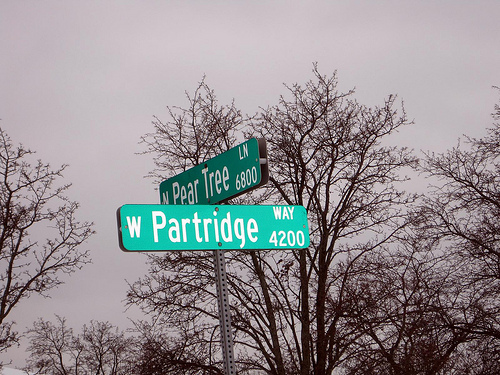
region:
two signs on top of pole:
[107, 125, 318, 370]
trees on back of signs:
[2, 42, 493, 373]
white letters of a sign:
[108, 193, 316, 260]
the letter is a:
[165, 215, 182, 249]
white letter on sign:
[125, 213, 142, 238]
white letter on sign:
[151, 208, 167, 245]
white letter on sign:
[166, 215, 181, 243]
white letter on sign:
[180, 216, 190, 243]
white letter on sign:
[190, 208, 202, 242]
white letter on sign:
[202, 215, 214, 245]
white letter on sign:
[211, 208, 223, 242]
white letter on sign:
[219, 210, 234, 243]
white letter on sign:
[232, 216, 247, 249]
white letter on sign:
[244, 215, 261, 243]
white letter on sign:
[160, 190, 171, 204]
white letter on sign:
[171, 180, 180, 205]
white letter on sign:
[178, 186, 188, 203]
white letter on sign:
[186, 180, 195, 204]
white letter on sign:
[191, 175, 201, 201]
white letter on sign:
[207, 170, 217, 196]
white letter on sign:
[212, 167, 223, 194]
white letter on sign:
[219, 166, 231, 194]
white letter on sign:
[237, 145, 244, 163]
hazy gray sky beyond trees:
[2, 2, 497, 374]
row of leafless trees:
[2, 59, 498, 374]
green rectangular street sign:
[110, 200, 317, 259]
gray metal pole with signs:
[201, 220, 247, 374]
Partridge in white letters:
[147, 208, 262, 250]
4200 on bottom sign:
[267, 228, 306, 253]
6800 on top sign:
[232, 162, 258, 194]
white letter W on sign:
[122, 213, 144, 243]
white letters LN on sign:
[231, 138, 251, 163]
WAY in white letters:
[267, 203, 297, 225]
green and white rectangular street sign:
[108, 198, 312, 257]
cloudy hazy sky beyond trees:
[2, 3, 497, 372]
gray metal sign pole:
[206, 238, 245, 372]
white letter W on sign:
[121, 211, 146, 238]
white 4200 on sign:
[265, 225, 305, 252]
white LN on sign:
[230, 140, 250, 162]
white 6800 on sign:
[227, 163, 259, 195]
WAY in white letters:
[268, 201, 296, 221]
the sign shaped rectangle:
[147, 131, 275, 208]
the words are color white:
[151, 129, 271, 210]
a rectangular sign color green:
[109, 196, 319, 254]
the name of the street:
[126, 205, 308, 249]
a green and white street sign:
[110, 130, 320, 374]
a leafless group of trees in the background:
[4, 58, 498, 373]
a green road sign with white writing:
[116, 203, 307, 250]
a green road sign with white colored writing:
[158, 135, 266, 206]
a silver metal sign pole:
[212, 248, 236, 373]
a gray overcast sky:
[1, 0, 498, 372]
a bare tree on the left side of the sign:
[1, 126, 87, 357]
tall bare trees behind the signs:
[134, 61, 394, 373]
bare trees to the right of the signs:
[338, 82, 498, 374]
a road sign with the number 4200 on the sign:
[115, 203, 312, 251]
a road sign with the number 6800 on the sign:
[161, 135, 265, 204]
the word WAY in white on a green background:
[269, 206, 296, 221]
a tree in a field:
[1, 123, 93, 361]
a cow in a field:
[23, 312, 123, 373]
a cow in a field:
[130, 76, 292, 373]